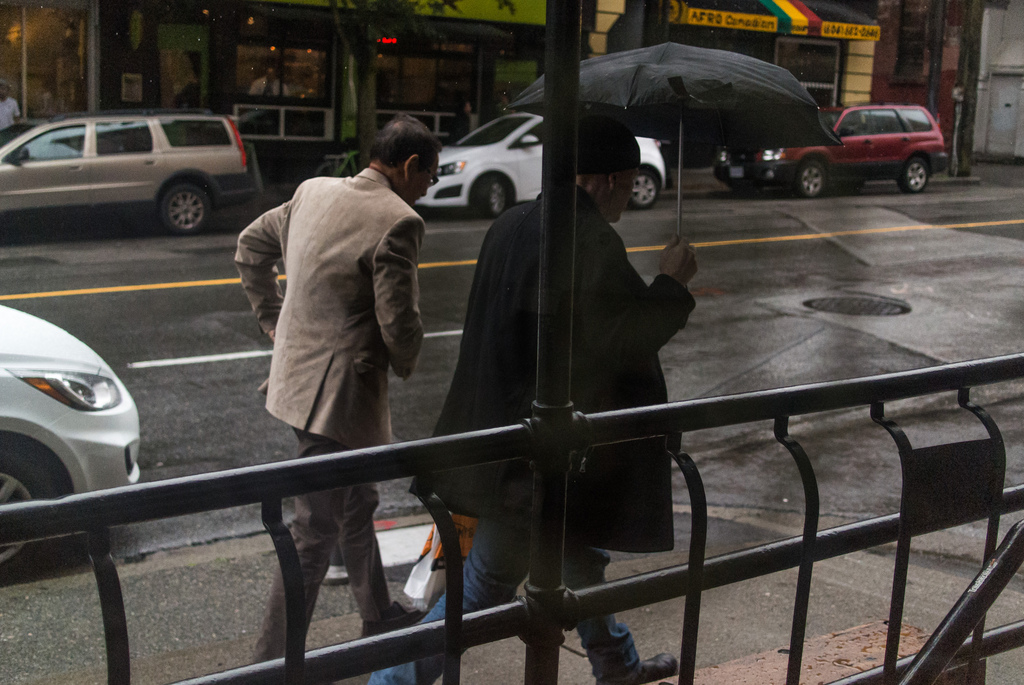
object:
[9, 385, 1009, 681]
sidewalk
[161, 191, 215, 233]
wheel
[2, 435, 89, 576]
wheel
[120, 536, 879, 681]
sidewalk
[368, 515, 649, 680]
jeans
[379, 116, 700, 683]
man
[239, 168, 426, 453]
blazer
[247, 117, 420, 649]
man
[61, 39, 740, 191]
wall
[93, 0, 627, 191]
building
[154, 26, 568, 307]
wall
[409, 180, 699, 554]
coat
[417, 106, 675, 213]
car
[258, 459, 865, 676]
sidewalk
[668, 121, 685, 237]
pole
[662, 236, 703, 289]
hand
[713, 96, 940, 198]
suv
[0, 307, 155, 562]
car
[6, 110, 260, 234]
car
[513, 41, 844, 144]
umbrella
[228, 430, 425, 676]
pants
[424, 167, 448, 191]
glasses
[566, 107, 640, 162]
hat